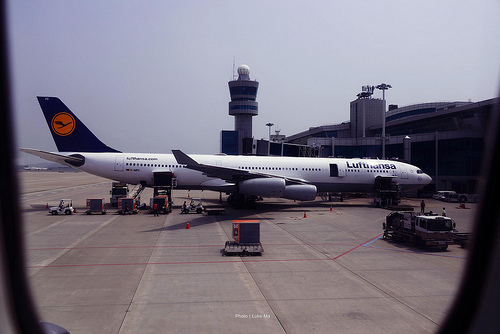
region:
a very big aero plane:
[29, 119, 449, 230]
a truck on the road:
[203, 209, 296, 272]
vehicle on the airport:
[361, 186, 471, 263]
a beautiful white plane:
[32, 117, 443, 218]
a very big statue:
[200, 56, 285, 145]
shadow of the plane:
[132, 211, 221, 239]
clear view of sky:
[55, 17, 497, 116]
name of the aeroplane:
[338, 154, 413, 185]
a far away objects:
[352, 74, 402, 100]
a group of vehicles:
[36, 192, 186, 225]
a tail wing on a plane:
[29, 94, 126, 154]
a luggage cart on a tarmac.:
[213, 206, 277, 261]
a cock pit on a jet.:
[406, 162, 431, 193]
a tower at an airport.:
[232, 59, 269, 151]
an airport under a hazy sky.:
[219, 59, 499, 203]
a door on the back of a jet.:
[111, 149, 135, 179]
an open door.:
[326, 160, 348, 182]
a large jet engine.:
[167, 148, 318, 197]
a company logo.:
[338, 162, 410, 176]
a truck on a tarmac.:
[361, 185, 458, 253]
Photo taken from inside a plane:
[7, 5, 496, 330]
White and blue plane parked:
[22, 73, 459, 210]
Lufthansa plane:
[342, 157, 406, 175]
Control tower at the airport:
[216, 42, 271, 165]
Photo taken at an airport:
[7, 10, 489, 321]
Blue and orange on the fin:
[28, 74, 133, 160]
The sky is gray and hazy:
[20, 10, 487, 164]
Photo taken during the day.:
[8, 8, 490, 332]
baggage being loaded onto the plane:
[142, 166, 179, 220]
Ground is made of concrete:
[26, 167, 495, 327]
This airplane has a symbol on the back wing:
[43, 105, 85, 142]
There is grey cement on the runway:
[183, 291, 223, 331]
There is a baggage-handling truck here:
[386, 196, 453, 252]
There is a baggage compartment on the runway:
[226, 217, 263, 259]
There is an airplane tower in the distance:
[218, 46, 279, 144]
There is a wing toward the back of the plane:
[26, 145, 66, 185]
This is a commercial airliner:
[74, 77, 459, 251]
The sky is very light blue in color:
[124, 22, 144, 57]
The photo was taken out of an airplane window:
[468, 220, 499, 302]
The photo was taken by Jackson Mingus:
[96, 33, 374, 331]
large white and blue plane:
[41, 65, 469, 256]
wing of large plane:
[161, 145, 321, 229]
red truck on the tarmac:
[202, 212, 263, 280]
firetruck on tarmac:
[361, 207, 473, 278]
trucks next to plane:
[85, 157, 182, 228]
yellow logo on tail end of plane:
[40, 100, 81, 170]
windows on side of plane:
[108, 161, 369, 175]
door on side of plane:
[308, 160, 349, 197]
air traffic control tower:
[151, 52, 263, 209]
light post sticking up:
[358, 81, 398, 166]